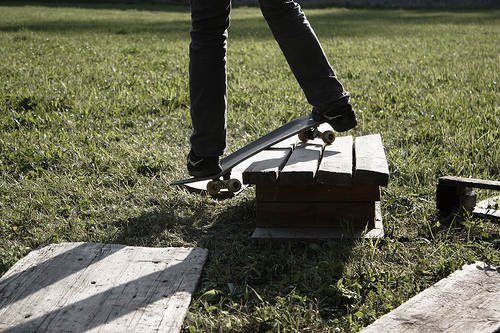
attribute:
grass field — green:
[384, 27, 499, 170]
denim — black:
[192, 3, 342, 150]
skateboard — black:
[250, 130, 283, 155]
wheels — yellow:
[297, 122, 336, 148]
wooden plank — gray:
[15, 241, 197, 331]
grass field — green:
[0, 0, 499, 331]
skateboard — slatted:
[159, 106, 365, 200]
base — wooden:
[224, 127, 411, 264]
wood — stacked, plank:
[355, 129, 392, 192]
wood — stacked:
[319, 135, 355, 187]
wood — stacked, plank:
[280, 133, 317, 188]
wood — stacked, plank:
[246, 122, 282, 186]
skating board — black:
[167, 111, 336, 198]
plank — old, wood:
[250, 104, 399, 232]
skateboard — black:
[161, 94, 356, 197]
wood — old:
[437, 157, 499, 222]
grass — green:
[432, 21, 450, 90]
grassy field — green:
[3, 2, 498, 234]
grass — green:
[31, 133, 71, 168]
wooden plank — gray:
[358, 260, 498, 331]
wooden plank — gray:
[0, 233, 210, 331]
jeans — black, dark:
[181, 0, 358, 177]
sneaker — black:
[304, 87, 359, 139]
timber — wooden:
[242, 133, 389, 241]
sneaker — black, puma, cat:
[174, 146, 224, 179]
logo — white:
[187, 155, 202, 170]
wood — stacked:
[243, 127, 395, 248]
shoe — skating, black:
[315, 82, 371, 141]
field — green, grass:
[59, 35, 194, 175]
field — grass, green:
[387, 17, 477, 114]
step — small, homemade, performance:
[214, 129, 465, 198]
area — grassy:
[2, 12, 482, 327]